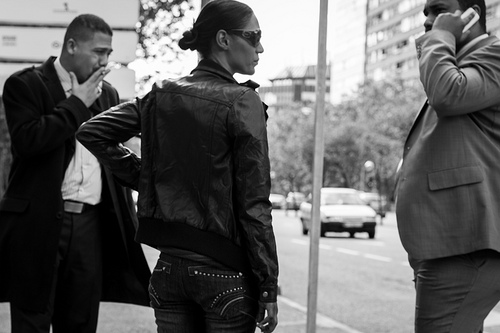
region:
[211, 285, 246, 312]
metal studs on the pants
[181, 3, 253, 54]
her hair is in a bun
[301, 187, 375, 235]
a car driving on the road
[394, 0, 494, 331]
the man is wearing a business suit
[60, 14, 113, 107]
the man is holding is hand to his mouth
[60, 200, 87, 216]
a metal belt clip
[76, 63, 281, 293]
a dark leather jacket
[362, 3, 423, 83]
a building with windows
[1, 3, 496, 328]
three people standing on the side of the road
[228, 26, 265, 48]
sunglasses on her face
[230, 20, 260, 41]
The sunglasses the lady is wearing.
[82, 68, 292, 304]
The leather jacket the lady is wearing.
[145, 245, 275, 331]
The jeans the lady is wearing.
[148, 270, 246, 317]
The design on the lady's jeans.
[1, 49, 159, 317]
The black coat the man is wearing.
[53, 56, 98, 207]
The white shirt the man is wearing.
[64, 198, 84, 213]
The belt buckle the man is wearing.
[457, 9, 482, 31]
The phone the man is using.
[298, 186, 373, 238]
The white car in the street.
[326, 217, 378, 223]
The headlights of the white car in the street.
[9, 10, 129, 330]
person standing on street corner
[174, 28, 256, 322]
person standing on street corner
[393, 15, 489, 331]
person standing on street corner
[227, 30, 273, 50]
sunglasses on woman's face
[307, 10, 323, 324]
metal pole on corner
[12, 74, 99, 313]
black coat on man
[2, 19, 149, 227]
building behind man on left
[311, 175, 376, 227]
car on paves road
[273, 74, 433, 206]
trees growing across street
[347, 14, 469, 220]
tall building on right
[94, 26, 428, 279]
a woman standing outside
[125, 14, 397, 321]
a woman standing on a sidewalkk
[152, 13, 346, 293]
a woman wearing sunglasses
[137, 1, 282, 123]
a woman with her hair up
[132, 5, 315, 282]
a woman weawring a jacket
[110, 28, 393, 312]
a woman wearing a leather jacket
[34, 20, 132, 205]
a man smoking a cigeratte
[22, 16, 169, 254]
a man with a cigarette in his mouth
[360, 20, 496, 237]
a man talking on a phone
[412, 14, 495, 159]
a man talking on a cell phone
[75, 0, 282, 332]
A woman in a leather coat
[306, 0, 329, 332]
A sign post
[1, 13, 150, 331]
A man who is smoking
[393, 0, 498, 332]
A man who is on a cell phone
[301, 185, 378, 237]
A small white car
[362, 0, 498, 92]
A sky scraper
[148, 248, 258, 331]
A pair of jeans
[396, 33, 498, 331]
A man's suit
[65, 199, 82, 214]
A belt buckle